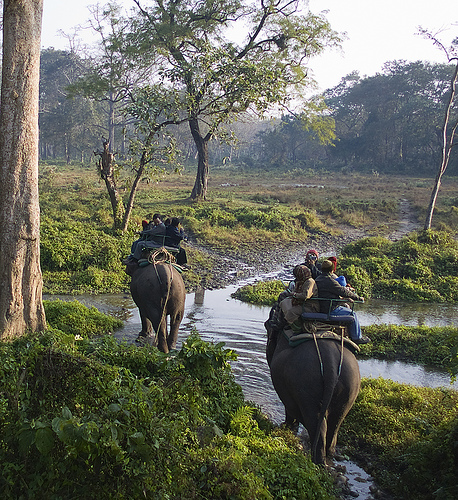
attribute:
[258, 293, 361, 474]
elephant — gray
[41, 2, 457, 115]
sky — light blue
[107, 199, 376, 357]
people — enjoying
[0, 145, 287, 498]
grass — green, short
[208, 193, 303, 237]
grass — short, green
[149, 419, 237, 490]
grass — short, green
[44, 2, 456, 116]
clouds — white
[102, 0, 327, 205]
tree — tall, white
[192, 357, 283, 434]
grass — green, short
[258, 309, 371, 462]
elephants — walking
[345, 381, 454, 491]
grass — green, short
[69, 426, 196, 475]
grass — short, green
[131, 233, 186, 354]
elephant — large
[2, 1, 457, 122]
clouds — white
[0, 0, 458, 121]
sky — light blue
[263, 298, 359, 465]
elephant — large, gray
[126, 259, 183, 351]
elephant — gray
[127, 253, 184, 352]
elephant — gray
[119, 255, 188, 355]
elephant — gray